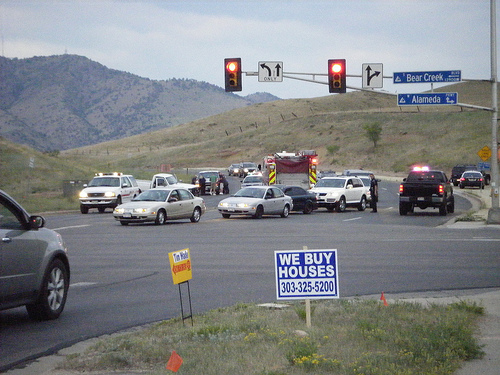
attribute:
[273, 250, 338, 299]
sign — white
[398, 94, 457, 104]
street sign — blue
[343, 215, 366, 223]
line — white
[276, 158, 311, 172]
flag — red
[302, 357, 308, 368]
flower — yellow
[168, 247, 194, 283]
sign — yellow, red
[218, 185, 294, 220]
sedan — silver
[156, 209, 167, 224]
tire — black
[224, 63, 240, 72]
traffic light — red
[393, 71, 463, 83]
street sign — blue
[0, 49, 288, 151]
hill — rocky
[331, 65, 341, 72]
traffic light — red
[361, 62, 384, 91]
traffic sign — white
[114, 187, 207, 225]
car — gold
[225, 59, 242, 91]
traffic light — red